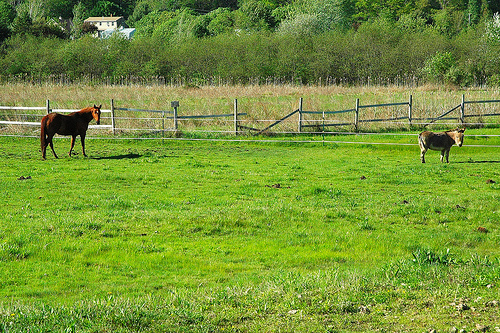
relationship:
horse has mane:
[32, 101, 102, 159] [73, 104, 93, 114]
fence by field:
[3, 103, 498, 128] [7, 127, 494, 329]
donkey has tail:
[416, 121, 471, 168] [417, 135, 431, 158]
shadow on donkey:
[448, 159, 498, 162] [416, 126, 464, 163]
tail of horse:
[39, 117, 48, 152] [37, 101, 103, 158]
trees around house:
[1, 2, 497, 79] [78, 12, 138, 38]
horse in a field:
[32, 101, 102, 159] [2, 0, 497, 330]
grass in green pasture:
[2, 125, 497, 330] [0, 132, 499, 330]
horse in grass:
[32, 101, 102, 159] [9, 140, 479, 290]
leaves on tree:
[174, 41, 316, 66] [29, 27, 499, 87]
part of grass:
[416, 137, 428, 145] [2, 125, 497, 330]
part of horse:
[252, 107, 273, 125] [406, 110, 474, 181]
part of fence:
[252, 107, 273, 125] [5, 98, 491, 140]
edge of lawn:
[9, 308, 480, 331] [40, 163, 480, 315]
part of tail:
[417, 137, 421, 145] [406, 107, 442, 158]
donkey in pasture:
[416, 126, 465, 164] [2, 129, 499, 331]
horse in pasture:
[39, 103, 102, 160] [2, 129, 499, 331]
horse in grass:
[39, 103, 102, 160] [219, 236, 483, 302]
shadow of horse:
[94, 149, 143, 159] [39, 102, 99, 158]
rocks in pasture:
[411, 294, 499, 331] [2, 129, 499, 331]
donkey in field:
[416, 126, 465, 164] [7, 127, 494, 329]